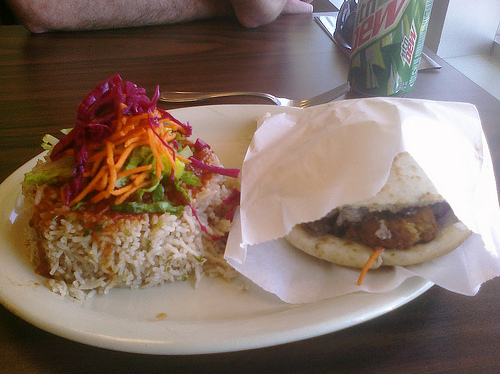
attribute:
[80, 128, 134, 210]
carrots — sliced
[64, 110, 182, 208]
carrots — orange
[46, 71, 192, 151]
cabbage — red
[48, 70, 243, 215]
cabbage — red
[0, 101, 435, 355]
plate — white, large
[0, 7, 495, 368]
table — dark brown, wood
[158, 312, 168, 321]
crumbs — brown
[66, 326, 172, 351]
edge — shiny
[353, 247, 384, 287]
carrot piece — small, orange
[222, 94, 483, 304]
bag — white, paper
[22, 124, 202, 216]
lettuce — thin-sliced, green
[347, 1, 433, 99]
soda can — green, white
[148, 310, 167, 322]
crumb — small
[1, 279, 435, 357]
edge — shiny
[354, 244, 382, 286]
carrot slice — orange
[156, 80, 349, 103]
fork — long, silver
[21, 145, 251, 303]
rice — white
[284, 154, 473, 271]
bun — white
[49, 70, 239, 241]
vegetable — purple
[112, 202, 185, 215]
lettuce sliver — green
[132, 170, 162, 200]
lettuce sliver — green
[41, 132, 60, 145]
lettuce sliver — green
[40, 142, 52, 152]
lettuce sliver — green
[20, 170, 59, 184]
lettuce sliver — green